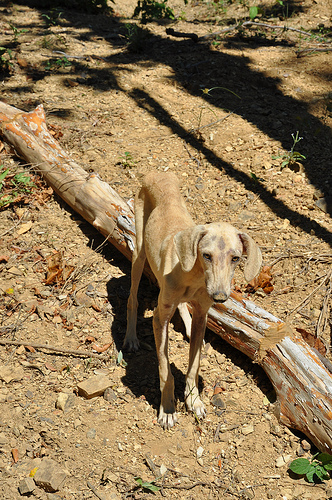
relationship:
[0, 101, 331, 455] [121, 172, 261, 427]
log behind dog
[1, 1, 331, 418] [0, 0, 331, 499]
shadows on ground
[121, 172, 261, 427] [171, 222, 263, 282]
dog has ears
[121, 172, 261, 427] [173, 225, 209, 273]
dog has an ear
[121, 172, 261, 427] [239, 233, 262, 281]
dog has an ear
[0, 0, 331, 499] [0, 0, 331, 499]
leaves are on ground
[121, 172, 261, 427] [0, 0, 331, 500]
dog out in daytime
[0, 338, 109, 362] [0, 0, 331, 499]
stick on ground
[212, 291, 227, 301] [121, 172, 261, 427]
dirt on dog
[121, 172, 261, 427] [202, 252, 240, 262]
dog has sad eyes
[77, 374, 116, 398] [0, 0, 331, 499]
brick on ground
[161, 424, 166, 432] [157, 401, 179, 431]
nail on foot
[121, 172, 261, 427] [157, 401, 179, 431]
dog has a foot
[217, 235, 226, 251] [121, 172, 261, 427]
gray spot on dog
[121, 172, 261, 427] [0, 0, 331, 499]
dog on ground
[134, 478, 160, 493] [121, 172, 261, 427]
leaf near dog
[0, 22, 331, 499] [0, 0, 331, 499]
twigs on ground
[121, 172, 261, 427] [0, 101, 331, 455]
dog standing in front of log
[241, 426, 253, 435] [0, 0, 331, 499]
rock on ground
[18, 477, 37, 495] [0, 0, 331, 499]
rock on ground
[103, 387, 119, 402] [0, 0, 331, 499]
rock on ground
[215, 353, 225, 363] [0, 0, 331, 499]
rock on ground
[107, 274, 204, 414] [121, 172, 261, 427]
shadow of dog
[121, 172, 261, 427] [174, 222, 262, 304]
dog has a head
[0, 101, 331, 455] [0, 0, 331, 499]
log on ground